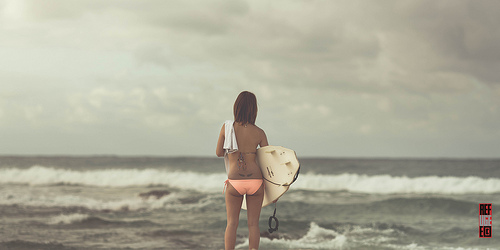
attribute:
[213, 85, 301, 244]
woman — standing, looking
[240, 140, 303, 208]
surfboard — white, here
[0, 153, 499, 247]
water — choppy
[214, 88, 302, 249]
girl — facing, surfer, standing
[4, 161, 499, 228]
waves — choppy, here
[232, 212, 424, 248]
surf — breaking, here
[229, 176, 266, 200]
bikini bottom — pink, peach colored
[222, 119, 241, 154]
shirt — draped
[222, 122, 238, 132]
shoulder — girl's, woman's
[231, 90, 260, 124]
hair — short, dark, straight, brunette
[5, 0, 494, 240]
weather — overcast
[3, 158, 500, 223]
wave — crashing, long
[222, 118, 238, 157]
towel — draped, white, beach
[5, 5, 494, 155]
sky — gray, cloudy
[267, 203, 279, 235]
tether — hanging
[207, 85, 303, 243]
view — woman, back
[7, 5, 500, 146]
clouds — gray, puffy, overcast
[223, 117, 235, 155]
something — white, draped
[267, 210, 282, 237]
strap — black, hanging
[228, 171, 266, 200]
bikini bottoms — light pink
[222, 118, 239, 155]
fabric — white, hanging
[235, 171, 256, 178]
tattoo — here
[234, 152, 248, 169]
strings — hanging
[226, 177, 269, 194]
bottoms — woman's, swimsuit's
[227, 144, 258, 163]
top — woman's, swimsuit's